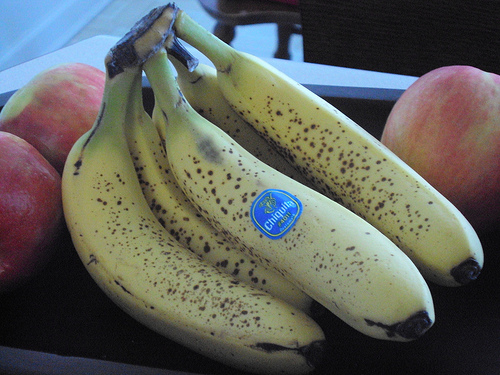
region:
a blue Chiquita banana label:
[244, 188, 307, 239]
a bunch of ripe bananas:
[60, 4, 485, 363]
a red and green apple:
[372, 64, 499, 225]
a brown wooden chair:
[194, 3, 306, 62]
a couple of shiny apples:
[2, 61, 129, 296]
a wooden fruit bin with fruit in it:
[3, 36, 499, 373]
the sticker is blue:
[241, 181, 308, 236]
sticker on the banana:
[251, 187, 302, 239]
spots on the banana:
[147, 233, 203, 296]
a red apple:
[9, 161, 36, 219]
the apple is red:
[419, 90, 491, 165]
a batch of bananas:
[102, 102, 422, 344]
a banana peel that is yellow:
[174, 131, 226, 185]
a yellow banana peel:
[346, 260, 412, 299]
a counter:
[76, 52, 101, 59]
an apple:
[40, 87, 85, 118]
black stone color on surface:
[40, 324, 116, 339]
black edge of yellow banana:
[398, 310, 441, 343]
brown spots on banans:
[137, 237, 204, 293]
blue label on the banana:
[228, 173, 335, 260]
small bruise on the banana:
[179, 135, 244, 170]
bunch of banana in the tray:
[59, 20, 468, 337]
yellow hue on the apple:
[405, 133, 430, 154]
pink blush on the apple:
[426, 78, 473, 114]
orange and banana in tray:
[22, 20, 483, 299]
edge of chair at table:
[203, 5, 323, 52]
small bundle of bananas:
[56, 7, 481, 372]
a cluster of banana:
[62, 4, 482, 372]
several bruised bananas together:
[56, 10, 483, 364]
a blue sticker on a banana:
[245, 185, 300, 240]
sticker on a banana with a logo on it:
[251, 186, 301, 239]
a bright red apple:
[385, 63, 497, 201]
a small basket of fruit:
[3, 5, 497, 365]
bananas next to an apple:
[63, 7, 498, 372]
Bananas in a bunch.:
[60, 0, 481, 365]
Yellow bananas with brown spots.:
[80, 128, 255, 318]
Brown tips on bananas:
[350, 253, 487, 342]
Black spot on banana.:
[187, 135, 236, 168]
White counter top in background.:
[5, 0, 425, 90]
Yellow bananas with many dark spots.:
[67, 14, 482, 356]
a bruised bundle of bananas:
[60, 3, 484, 368]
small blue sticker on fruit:
[249, 183, 303, 241]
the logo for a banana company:
[252, 188, 300, 236]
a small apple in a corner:
[385, 65, 499, 197]